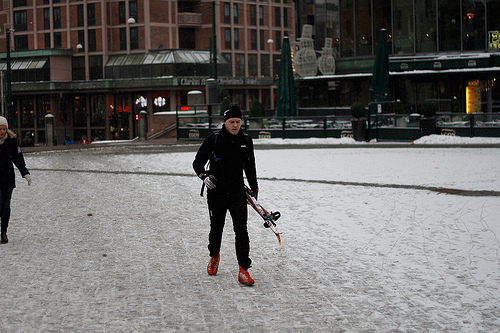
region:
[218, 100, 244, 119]
man has black hat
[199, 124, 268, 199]
man has black jacket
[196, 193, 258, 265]
man has black pants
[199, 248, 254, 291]
man has red shoes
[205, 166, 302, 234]
man is carrying skateboard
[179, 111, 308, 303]
man walks on sidewalk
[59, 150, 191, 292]
sidewalk is light grey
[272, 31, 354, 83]
two snowmen on building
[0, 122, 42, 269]
woman walks on sidewalk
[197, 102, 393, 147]
black fence behind man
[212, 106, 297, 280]
person is walking with skateboard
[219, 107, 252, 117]
man has black hat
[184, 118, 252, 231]
man has black shirt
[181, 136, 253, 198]
man has black and white gloves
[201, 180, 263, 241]
man has black pants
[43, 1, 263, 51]
white frame around windows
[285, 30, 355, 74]
white snowmen on building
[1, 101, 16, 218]
woman walking near man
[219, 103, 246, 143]
man wearing a beanie hat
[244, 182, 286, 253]
man carrying skis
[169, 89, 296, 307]
man walking across the pavement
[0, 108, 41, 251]
woman walking across the pavement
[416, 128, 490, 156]
snow on the sidewalk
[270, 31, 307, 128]
umbrella unopened on the sidewalk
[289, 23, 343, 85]
snowmen figures on the building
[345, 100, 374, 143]
round plant in the planter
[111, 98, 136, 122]
neon sign in the window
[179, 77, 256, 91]
business name on the side of the building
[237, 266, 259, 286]
a man's red shoe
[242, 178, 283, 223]
part of a black ski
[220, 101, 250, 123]
a man's black cap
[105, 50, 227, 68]
the roof of a building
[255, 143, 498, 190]
a section of white snow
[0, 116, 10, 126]
part of a woman's white cap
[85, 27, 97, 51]
the window of a building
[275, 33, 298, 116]
a tall green umbrella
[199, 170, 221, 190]
a black and white glove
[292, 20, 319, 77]
a white Christmas decoration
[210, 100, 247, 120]
the hat is black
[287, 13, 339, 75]
the snowmen are on the building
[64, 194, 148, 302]
the snow is on the ground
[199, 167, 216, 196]
the glove is gray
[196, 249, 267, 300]
the shoes are orange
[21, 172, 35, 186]
the glove is white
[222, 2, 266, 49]
the windows are on the building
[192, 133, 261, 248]
the clothes are black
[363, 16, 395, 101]
the umbrella is closed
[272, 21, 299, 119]
the umbrella is green